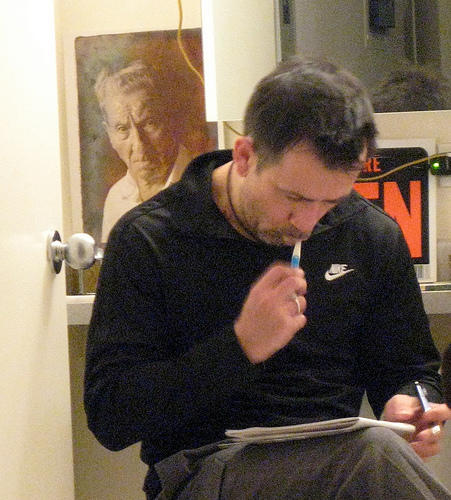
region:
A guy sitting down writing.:
[84, 61, 448, 498]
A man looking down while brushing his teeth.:
[72, 53, 449, 480]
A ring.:
[289, 294, 300, 316]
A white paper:
[226, 420, 422, 448]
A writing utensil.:
[409, 377, 445, 445]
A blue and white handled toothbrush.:
[286, 237, 309, 272]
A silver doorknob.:
[46, 229, 103, 273]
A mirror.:
[273, 0, 448, 119]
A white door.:
[3, 1, 80, 499]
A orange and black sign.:
[349, 141, 435, 283]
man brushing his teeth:
[83, 54, 450, 499]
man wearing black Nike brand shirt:
[83, 53, 449, 498]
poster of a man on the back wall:
[62, 26, 225, 292]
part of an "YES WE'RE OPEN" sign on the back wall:
[352, 138, 437, 281]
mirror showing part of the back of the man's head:
[272, 2, 450, 110]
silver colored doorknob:
[48, 228, 104, 272]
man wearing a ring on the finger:
[84, 53, 449, 499]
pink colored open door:
[6, 2, 101, 497]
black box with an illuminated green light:
[428, 153, 450, 173]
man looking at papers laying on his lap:
[80, 56, 445, 499]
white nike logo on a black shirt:
[320, 260, 356, 283]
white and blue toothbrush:
[287, 234, 303, 276]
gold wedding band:
[289, 292, 301, 316]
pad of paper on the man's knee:
[215, 416, 420, 448]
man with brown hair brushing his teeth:
[73, 49, 449, 498]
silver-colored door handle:
[45, 225, 106, 277]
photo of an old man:
[77, 21, 223, 299]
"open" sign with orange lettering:
[342, 135, 441, 287]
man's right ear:
[230, 136, 258, 179]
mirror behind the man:
[267, 0, 449, 119]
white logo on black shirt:
[314, 256, 366, 287]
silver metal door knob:
[41, 228, 103, 273]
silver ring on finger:
[286, 293, 302, 314]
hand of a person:
[237, 258, 309, 360]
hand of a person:
[378, 389, 449, 470]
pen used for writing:
[412, 378, 442, 441]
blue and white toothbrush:
[282, 233, 311, 277]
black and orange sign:
[335, 134, 441, 281]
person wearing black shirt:
[67, 52, 443, 499]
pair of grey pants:
[132, 424, 449, 498]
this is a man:
[168, 97, 395, 468]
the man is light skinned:
[243, 282, 278, 336]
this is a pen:
[288, 246, 306, 265]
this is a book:
[281, 416, 333, 439]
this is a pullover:
[136, 230, 204, 316]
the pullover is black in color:
[160, 260, 210, 304]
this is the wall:
[9, 92, 65, 222]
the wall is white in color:
[7, 119, 66, 206]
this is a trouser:
[296, 443, 366, 497]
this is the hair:
[299, 97, 355, 133]